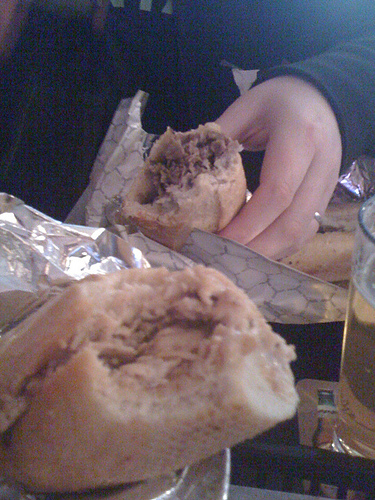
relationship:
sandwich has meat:
[28, 223, 332, 476] [138, 304, 214, 351]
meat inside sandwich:
[138, 304, 214, 351] [28, 223, 332, 476]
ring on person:
[300, 196, 340, 246] [108, 71, 331, 297]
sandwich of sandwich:
[0, 262, 300, 499] [28, 223, 332, 476]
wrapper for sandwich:
[3, 181, 134, 294] [28, 223, 332, 476]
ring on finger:
[300, 196, 340, 246] [185, 140, 295, 297]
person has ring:
[108, 71, 331, 297] [300, 196, 340, 246]